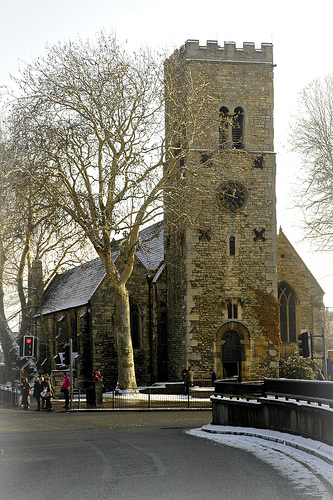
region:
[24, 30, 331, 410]
a old large church made of stone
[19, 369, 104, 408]
some people gathered infront o the church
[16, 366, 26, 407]
a street stop light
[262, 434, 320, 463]
some snow on the ground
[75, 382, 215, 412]
a small fence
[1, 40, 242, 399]
a very large tree with no leaves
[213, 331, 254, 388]
the church entrance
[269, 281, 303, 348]
a large church window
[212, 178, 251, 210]
a large clock on the church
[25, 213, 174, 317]
the roof of the church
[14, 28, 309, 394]
This is a church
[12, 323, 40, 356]
This is a traffic light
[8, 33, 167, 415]
Large tree next to church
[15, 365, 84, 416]
People standing next to stop light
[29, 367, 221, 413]
Black fence surrounding church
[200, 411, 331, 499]
Snow on the ground next to fence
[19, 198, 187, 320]
Snow on church rooftop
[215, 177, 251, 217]
Clock on church wall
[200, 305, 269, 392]
Door of the church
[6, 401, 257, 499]
Large intersection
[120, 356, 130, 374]
part of a stem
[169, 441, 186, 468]
part of a road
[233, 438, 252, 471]
edge of a road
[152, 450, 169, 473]
part of a lline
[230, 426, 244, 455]
part of a snow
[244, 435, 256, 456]
part of a snow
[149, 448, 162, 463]
part of a line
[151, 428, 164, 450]
par tof a road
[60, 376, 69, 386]
Person wearing pink coat.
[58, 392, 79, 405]
Person wearing black pants.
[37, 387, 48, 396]
Person holding white bag.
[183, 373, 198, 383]
Person wearing brown coat.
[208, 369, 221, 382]
Person wearing black coat.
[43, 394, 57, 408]
Person wearing black pants.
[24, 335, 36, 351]
Red light illuminated on traffic signal.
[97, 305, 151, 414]
Large tree near building.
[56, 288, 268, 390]
Large building on street corner.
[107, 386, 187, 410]
Black fence in front of building.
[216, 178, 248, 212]
Clock reading 12:50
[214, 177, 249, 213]
Black and gold clock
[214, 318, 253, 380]
Arch over doorway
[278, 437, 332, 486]
Tire track in snow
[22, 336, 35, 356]
Traffic signal turned red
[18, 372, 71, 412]
Pedestrians waiting to cross street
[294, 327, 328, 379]
Traffic signal attached to metal post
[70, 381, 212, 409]
Black metal fence lining street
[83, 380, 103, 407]
Black trash container behind fence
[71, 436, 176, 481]
Tire tracks in wet street